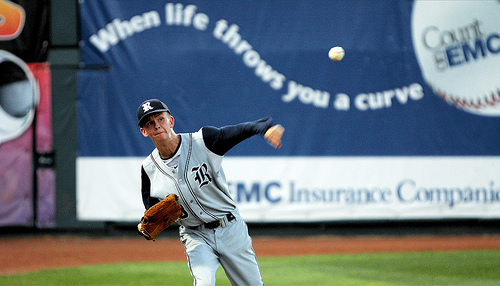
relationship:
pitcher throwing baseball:
[135, 99, 284, 285] [327, 44, 342, 59]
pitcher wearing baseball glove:
[135, 99, 284, 285] [139, 194, 186, 234]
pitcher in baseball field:
[135, 99, 284, 285] [2, 223, 499, 285]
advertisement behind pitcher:
[77, 0, 499, 222] [135, 99, 284, 285]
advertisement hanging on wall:
[77, 0, 499, 222] [0, 2, 499, 229]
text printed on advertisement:
[86, 2, 424, 108] [77, 0, 499, 222]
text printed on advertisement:
[423, 18, 499, 70] [77, 0, 499, 222]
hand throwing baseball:
[265, 124, 285, 147] [327, 44, 342, 59]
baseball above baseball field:
[327, 44, 342, 59] [2, 223, 499, 285]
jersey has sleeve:
[142, 117, 277, 228] [200, 117, 276, 156]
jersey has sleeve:
[142, 117, 277, 228] [141, 168, 163, 210]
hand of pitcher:
[265, 124, 285, 147] [135, 99, 284, 285]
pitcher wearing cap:
[135, 99, 284, 285] [135, 99, 165, 120]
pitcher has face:
[135, 99, 284, 285] [142, 113, 171, 138]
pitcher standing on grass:
[135, 99, 284, 285] [1, 249, 499, 284]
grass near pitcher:
[1, 249, 499, 284] [135, 99, 284, 285]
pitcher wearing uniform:
[135, 99, 284, 285] [139, 117, 279, 285]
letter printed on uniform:
[190, 165, 213, 185] [139, 117, 279, 285]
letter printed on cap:
[140, 101, 153, 113] [135, 99, 165, 120]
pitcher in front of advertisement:
[135, 99, 284, 285] [77, 0, 499, 222]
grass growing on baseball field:
[1, 249, 499, 284] [2, 223, 499, 285]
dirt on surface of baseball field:
[0, 233, 498, 274] [2, 223, 499, 285]